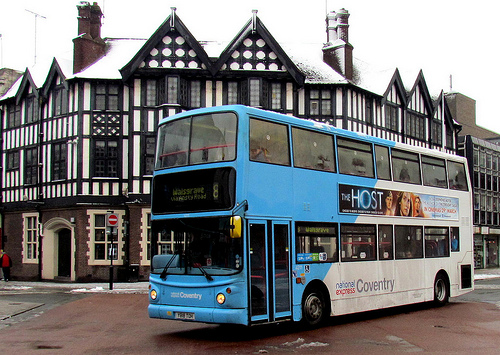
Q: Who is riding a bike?
A: No one.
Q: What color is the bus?
A: Blue and white.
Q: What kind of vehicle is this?
A: A bus.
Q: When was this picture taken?
A: Day time.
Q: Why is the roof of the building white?
A: There is snow on it.